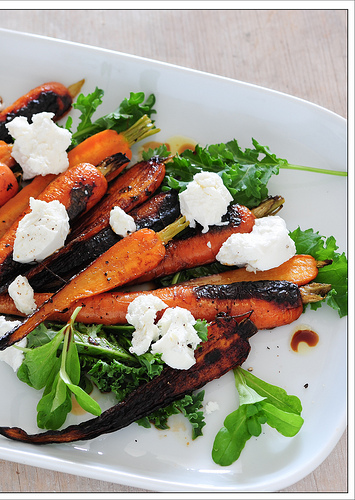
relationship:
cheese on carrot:
[214, 215, 296, 275] [119, 190, 285, 284]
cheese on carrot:
[178, 171, 234, 234] [119, 190, 285, 284]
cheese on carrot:
[13, 195, 69, 263] [119, 190, 285, 284]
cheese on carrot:
[5, 111, 72, 180] [119, 190, 285, 284]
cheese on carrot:
[120, 289, 206, 375] [119, 190, 285, 284]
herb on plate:
[213, 372, 307, 475] [21, 131, 345, 484]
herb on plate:
[10, 322, 108, 428] [21, 131, 345, 484]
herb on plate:
[291, 225, 351, 321] [21, 131, 345, 484]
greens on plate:
[161, 136, 347, 206] [21, 131, 345, 484]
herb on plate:
[59, 93, 154, 141] [21, 131, 345, 484]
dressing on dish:
[291, 329, 319, 351] [0, 26, 349, 496]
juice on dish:
[290, 327, 318, 351] [0, 26, 349, 496]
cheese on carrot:
[151, 306, 202, 371] [1, 84, 313, 449]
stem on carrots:
[111, 110, 164, 151] [2, 125, 149, 245]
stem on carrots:
[160, 212, 187, 244] [2, 125, 149, 245]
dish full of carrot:
[0, 26, 349, 496] [0, 318, 258, 443]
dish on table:
[0, 26, 349, 496] [1, 9, 350, 491]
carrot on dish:
[0, 157, 108, 270] [0, 26, 349, 496]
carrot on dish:
[0, 282, 330, 328] [0, 26, 349, 496]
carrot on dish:
[130, 195, 276, 277] [0, 26, 349, 496]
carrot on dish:
[0, 124, 132, 227] [0, 26, 349, 496]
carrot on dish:
[0, 78, 86, 144] [0, 26, 349, 496]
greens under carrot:
[161, 136, 347, 206] [0, 318, 258, 443]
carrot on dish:
[0, 214, 190, 351] [0, 26, 349, 496]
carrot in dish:
[0, 282, 330, 328] [0, 37, 316, 458]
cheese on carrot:
[8, 274, 38, 315] [0, 279, 333, 328]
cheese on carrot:
[8, 274, 38, 315] [2, 231, 167, 330]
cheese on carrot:
[8, 274, 38, 315] [0, 162, 108, 275]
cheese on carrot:
[8, 274, 38, 315] [118, 190, 268, 278]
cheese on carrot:
[8, 274, 38, 315] [5, 74, 81, 136]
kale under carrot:
[26, 318, 208, 440] [0, 318, 258, 443]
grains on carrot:
[100, 258, 121, 321] [2, 227, 166, 351]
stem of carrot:
[120, 114, 161, 149] [0, 124, 150, 232]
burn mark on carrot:
[67, 180, 95, 220] [3, 149, 127, 274]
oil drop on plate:
[284, 323, 324, 351] [26, 74, 333, 494]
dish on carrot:
[0, 26, 349, 496] [0, 318, 258, 443]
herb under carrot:
[17, 307, 102, 431] [0, 306, 258, 444]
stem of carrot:
[120, 114, 161, 149] [34, 222, 189, 313]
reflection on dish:
[197, 464, 238, 478] [0, 26, 349, 496]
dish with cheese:
[0, 26, 349, 496] [216, 216, 295, 271]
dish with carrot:
[0, 26, 349, 496] [0, 180, 234, 345]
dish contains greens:
[0, 26, 349, 496] [99, 95, 271, 170]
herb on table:
[59, 87, 155, 153] [1, 9, 350, 491]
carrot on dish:
[0, 318, 258, 443] [0, 26, 349, 496]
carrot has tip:
[0, 282, 330, 328] [2, 424, 60, 449]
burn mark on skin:
[193, 281, 307, 293] [0, 277, 304, 326]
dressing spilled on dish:
[291, 329, 319, 351] [0, 26, 349, 496]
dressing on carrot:
[291, 329, 319, 351] [0, 318, 258, 443]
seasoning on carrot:
[81, 294, 249, 311] [0, 318, 258, 443]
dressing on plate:
[288, 328, 321, 347] [80, 45, 337, 140]